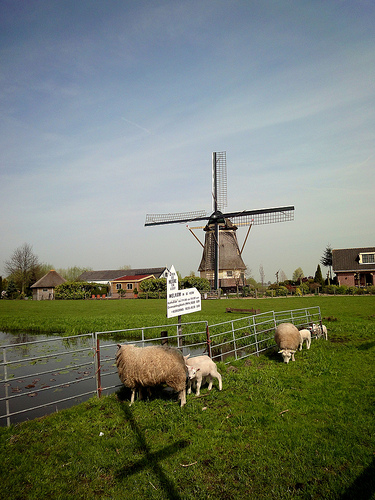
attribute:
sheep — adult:
[109, 337, 188, 409]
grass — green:
[4, 296, 368, 485]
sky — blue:
[145, 30, 295, 96]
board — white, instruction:
[167, 266, 203, 326]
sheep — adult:
[264, 319, 306, 373]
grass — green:
[33, 302, 346, 366]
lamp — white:
[149, 267, 162, 278]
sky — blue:
[206, 14, 300, 75]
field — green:
[4, 295, 332, 488]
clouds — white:
[15, 91, 289, 238]